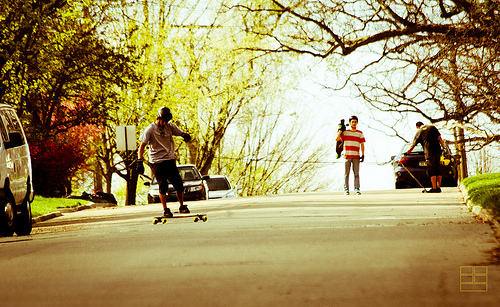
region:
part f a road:
[301, 238, 316, 260]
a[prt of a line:
[361, 213, 379, 237]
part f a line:
[304, 203, 339, 266]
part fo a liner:
[321, 202, 338, 218]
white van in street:
[0, 108, 33, 240]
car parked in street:
[203, 174, 238, 201]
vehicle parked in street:
[148, 157, 207, 202]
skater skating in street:
[136, 105, 203, 220]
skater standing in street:
[337, 118, 367, 197]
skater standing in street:
[402, 116, 452, 193]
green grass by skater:
[468, 167, 498, 214]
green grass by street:
[23, 187, 85, 214]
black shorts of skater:
[147, 160, 183, 192]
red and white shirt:
[341, 126, 363, 161]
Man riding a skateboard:
[136, 105, 209, 225]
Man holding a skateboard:
[334, 108, 367, 195]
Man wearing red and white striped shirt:
[335, 112, 368, 195]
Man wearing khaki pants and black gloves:
[335, 115, 367, 200]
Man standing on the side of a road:
[396, 119, 452, 194]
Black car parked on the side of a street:
[141, 165, 209, 200]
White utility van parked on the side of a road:
[0, 101, 39, 239]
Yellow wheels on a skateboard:
[151, 215, 210, 225]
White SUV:
[202, 172, 243, 202]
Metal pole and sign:
[114, 120, 139, 209]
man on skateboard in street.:
[137, 94, 207, 229]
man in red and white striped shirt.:
[331, 105, 369, 203]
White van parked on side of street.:
[0, 95, 32, 238]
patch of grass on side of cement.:
[462, 181, 497, 213]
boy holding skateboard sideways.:
[398, 114, 452, 192]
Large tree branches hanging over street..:
[271, 8, 491, 109]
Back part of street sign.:
[113, 120, 139, 160]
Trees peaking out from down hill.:
[251, 117, 316, 202]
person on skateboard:
[117, 89, 229, 249]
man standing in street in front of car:
[383, 106, 462, 195]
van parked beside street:
[0, 85, 54, 257]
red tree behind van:
[19, 70, 131, 227]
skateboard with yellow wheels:
[141, 172, 248, 255]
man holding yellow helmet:
[391, 103, 467, 216]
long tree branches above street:
[243, 0, 498, 141]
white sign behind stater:
[96, 101, 152, 203]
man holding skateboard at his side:
[313, 98, 388, 206]